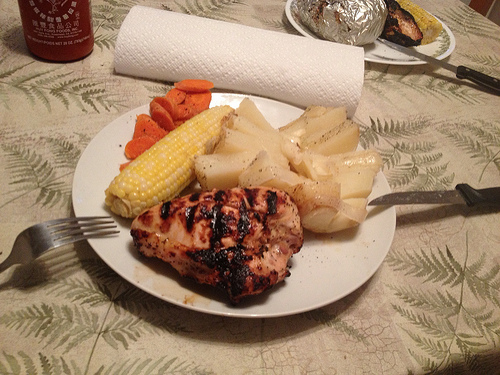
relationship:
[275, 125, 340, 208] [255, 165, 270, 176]
potato with pepper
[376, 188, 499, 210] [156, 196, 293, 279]
knife to cut chicken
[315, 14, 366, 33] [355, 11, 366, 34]
potato in foil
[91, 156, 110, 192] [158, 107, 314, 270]
plate has food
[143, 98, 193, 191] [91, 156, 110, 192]
vegetables on plate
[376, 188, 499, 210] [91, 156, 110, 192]
knife on plate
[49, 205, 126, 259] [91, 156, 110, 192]
fork on plate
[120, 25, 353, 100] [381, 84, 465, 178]
towels on top of table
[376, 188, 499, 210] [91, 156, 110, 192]
knife by plate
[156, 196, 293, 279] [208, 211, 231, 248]
chicken with sauce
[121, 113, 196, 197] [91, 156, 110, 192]
corn on plate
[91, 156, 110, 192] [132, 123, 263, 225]
plate with meal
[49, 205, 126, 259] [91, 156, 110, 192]
fork resting on plate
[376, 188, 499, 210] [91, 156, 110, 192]
knife resting on plate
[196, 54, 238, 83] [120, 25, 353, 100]
lines on towels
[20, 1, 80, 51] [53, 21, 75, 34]
bottle with writting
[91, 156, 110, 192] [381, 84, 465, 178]
plate on top of table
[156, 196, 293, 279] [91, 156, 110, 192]
chicken on plate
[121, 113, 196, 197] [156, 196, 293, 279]
corn by chicken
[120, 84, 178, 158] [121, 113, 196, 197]
carrots by corn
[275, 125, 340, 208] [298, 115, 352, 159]
potato in wedges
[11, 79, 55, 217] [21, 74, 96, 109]
tablecloth with design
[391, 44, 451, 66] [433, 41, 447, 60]
plate has design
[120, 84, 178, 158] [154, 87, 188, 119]
carrots in pile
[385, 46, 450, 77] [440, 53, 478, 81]
blade of knife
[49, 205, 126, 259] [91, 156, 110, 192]
fork on edge of plate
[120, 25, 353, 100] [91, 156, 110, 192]
towels by plate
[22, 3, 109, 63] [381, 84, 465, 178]
sauce on top of table